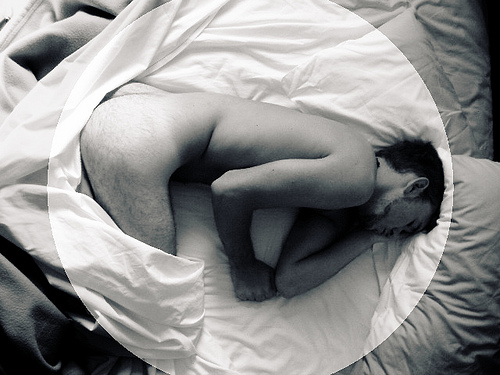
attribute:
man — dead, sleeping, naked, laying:
[81, 81, 446, 302]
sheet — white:
[1, 2, 204, 372]